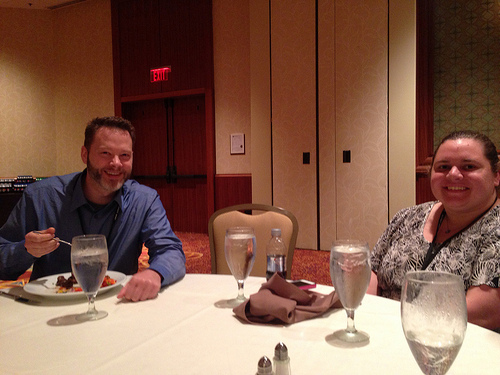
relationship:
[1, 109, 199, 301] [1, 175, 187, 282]
man wearing shirt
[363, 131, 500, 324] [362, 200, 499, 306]
woman wearing shirt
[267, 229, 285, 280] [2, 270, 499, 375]
bottle on table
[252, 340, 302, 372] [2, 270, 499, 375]
shaker on table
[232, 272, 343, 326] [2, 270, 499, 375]
cloth on table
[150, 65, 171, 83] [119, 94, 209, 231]
sign above door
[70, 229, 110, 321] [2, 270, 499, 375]
glass on table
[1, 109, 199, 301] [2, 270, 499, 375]
man at table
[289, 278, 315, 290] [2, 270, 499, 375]
phone at table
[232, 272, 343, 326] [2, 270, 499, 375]
cloth at table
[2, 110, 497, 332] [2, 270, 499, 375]
people at table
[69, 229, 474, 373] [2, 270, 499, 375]
glasses at table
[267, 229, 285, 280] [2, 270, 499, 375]
bottle at table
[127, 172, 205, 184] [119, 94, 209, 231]
bar on door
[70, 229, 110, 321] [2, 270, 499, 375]
glass at table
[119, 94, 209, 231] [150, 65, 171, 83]
doors below sign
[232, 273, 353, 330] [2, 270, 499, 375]
cloth on table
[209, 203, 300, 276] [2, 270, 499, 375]
chair at table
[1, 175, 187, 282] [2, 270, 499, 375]
shirt at table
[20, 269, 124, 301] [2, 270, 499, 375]
plate at table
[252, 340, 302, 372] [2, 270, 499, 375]
shaker at table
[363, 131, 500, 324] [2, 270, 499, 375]
woman at table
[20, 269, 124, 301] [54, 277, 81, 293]
plate with food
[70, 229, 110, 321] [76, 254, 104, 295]
glass of water